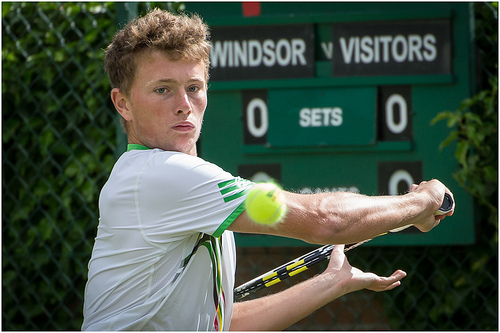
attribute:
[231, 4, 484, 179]
scoreboard — green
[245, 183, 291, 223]
tennis ball — green, yellow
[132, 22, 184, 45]
hair — curly, dark blond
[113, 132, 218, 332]
shirt — white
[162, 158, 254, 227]
sleeve — green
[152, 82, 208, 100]
eyes — blue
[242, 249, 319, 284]
tennis racquet — black, swinging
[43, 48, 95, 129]
fence — chain link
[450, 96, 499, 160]
greenery — tall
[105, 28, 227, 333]
man — young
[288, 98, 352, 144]
set — 0, word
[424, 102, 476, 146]
leaves — green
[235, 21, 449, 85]
sign — black, windsor